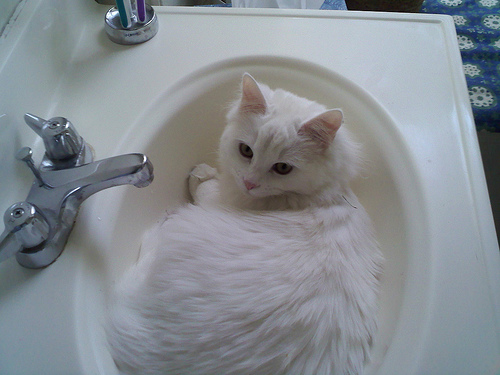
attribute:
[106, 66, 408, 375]
cat — white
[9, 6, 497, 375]
sink — white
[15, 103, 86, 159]
valve — cold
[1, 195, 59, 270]
valve — hot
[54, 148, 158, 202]
faucet — silver, chrome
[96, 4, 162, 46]
holder — chrome, decorative, silver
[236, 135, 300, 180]
eye — yellow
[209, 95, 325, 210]
face — long haired